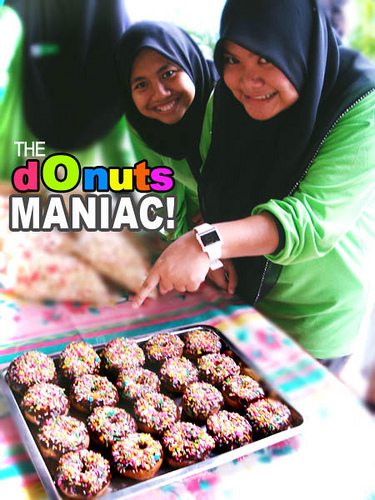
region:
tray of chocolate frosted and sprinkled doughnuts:
[5, 315, 314, 498]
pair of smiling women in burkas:
[4, 4, 373, 368]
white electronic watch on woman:
[192, 220, 230, 271]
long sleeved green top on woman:
[136, 77, 372, 373]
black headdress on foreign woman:
[189, 0, 374, 309]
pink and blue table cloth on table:
[3, 190, 374, 491]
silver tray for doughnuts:
[6, 315, 293, 498]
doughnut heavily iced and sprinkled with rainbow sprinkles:
[2, 342, 59, 395]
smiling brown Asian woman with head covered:
[115, 16, 211, 134]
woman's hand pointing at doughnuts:
[129, 211, 270, 313]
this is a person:
[132, 0, 371, 347]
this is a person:
[109, 16, 219, 235]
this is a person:
[0, 0, 128, 162]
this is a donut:
[53, 452, 108, 498]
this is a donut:
[113, 437, 166, 476]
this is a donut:
[169, 422, 208, 462]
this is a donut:
[202, 407, 248, 447]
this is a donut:
[244, 398, 287, 438]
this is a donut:
[84, 403, 138, 452]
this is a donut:
[135, 386, 175, 428]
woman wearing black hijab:
[195, 0, 372, 318]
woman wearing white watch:
[186, 215, 235, 271]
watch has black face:
[186, 218, 232, 268]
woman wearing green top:
[203, 98, 373, 350]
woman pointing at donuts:
[109, 217, 238, 330]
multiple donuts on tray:
[0, 322, 324, 498]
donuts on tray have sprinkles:
[10, 317, 296, 493]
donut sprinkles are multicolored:
[0, 341, 76, 409]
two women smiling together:
[85, 3, 338, 151]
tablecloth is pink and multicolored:
[21, 284, 181, 341]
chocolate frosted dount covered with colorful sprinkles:
[55, 448, 117, 499]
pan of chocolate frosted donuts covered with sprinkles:
[0, 323, 308, 498]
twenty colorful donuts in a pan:
[0, 320, 308, 499]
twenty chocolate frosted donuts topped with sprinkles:
[1, 323, 309, 499]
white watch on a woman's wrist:
[193, 219, 221, 268]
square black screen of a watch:
[195, 228, 221, 245]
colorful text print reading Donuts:
[10, 150, 177, 191]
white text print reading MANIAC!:
[6, 191, 178, 231]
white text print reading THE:
[11, 137, 45, 156]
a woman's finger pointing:
[127, 268, 161, 311]